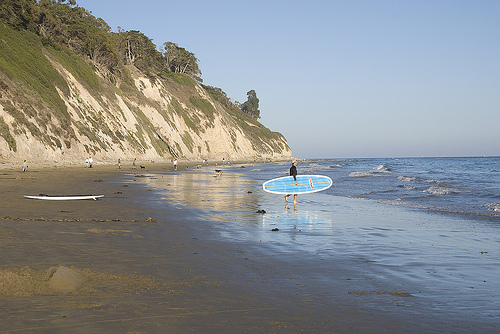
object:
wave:
[339, 153, 387, 167]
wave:
[422, 164, 453, 175]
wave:
[476, 197, 498, 211]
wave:
[391, 179, 428, 191]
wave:
[452, 152, 480, 182]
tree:
[80, 18, 113, 54]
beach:
[0, 167, 499, 332]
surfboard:
[19, 193, 105, 202]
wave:
[349, 160, 390, 177]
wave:
[398, 174, 424, 181]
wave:
[428, 186, 463, 195]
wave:
[308, 160, 339, 170]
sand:
[6, 245, 123, 301]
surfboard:
[261, 174, 333, 194]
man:
[284, 160, 301, 205]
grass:
[3, 34, 65, 152]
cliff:
[3, 10, 298, 166]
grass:
[120, 37, 282, 156]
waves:
[475, 154, 496, 192]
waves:
[340, 178, 401, 192]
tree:
[241, 88, 262, 116]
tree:
[159, 42, 198, 77]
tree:
[120, 30, 140, 67]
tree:
[50, 0, 68, 46]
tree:
[27, 4, 54, 36]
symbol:
[308, 178, 316, 189]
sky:
[50, 1, 498, 163]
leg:
[292, 192, 299, 205]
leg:
[283, 193, 291, 203]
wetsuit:
[288, 164, 299, 181]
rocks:
[78, 123, 200, 155]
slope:
[47, 38, 133, 160]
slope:
[200, 83, 290, 157]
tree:
[130, 29, 159, 74]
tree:
[0, 0, 22, 29]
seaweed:
[334, 279, 430, 311]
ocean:
[227, 157, 499, 227]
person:
[239, 165, 246, 169]